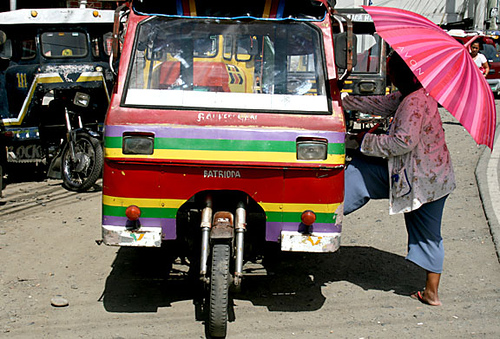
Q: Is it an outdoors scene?
A: Yes, it is outdoors.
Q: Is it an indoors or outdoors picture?
A: It is outdoors.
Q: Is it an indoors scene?
A: No, it is outdoors.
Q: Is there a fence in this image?
A: No, there are no fences.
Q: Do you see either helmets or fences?
A: No, there are no fences or helmets.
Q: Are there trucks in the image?
A: No, there are no trucks.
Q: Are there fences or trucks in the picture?
A: No, there are no trucks or fences.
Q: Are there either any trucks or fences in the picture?
A: No, there are no trucks or fences.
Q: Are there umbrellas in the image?
A: Yes, there is an umbrella.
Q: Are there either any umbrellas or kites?
A: Yes, there is an umbrella.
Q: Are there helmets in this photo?
A: No, there are no helmets.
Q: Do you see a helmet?
A: No, there are no helmets.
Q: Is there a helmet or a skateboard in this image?
A: No, there are no helmets or skateboards.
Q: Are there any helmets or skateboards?
A: No, there are no helmets or skateboards.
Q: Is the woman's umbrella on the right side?
A: Yes, the umbrella is on the right of the image.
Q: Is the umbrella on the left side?
A: No, the umbrella is on the right of the image.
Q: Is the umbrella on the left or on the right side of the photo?
A: The umbrella is on the right of the image.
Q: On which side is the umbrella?
A: The umbrella is on the right of the image.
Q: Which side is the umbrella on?
A: The umbrella is on the right of the image.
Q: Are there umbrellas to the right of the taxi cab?
A: Yes, there is an umbrella to the right of the taxi cab.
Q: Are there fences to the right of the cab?
A: No, there is an umbrella to the right of the cab.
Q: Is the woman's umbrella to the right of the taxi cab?
A: Yes, the umbrella is to the right of the taxi cab.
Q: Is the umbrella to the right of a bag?
A: No, the umbrella is to the right of the taxi cab.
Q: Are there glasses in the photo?
A: No, there are no glasses.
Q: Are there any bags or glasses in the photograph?
A: No, there are no glasses or bags.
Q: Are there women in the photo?
A: Yes, there is a woman.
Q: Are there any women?
A: Yes, there is a woman.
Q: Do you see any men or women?
A: Yes, there is a woman.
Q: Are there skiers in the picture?
A: No, there are no skiers.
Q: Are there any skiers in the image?
A: No, there are no skiers.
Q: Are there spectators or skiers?
A: No, there are no skiers or spectators.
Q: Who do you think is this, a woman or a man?
A: This is a woman.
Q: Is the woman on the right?
A: Yes, the woman is on the right of the image.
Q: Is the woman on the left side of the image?
A: No, the woman is on the right of the image.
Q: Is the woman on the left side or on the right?
A: The woman is on the right of the image.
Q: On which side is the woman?
A: The woman is on the right of the image.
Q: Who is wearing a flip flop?
A: The woman is wearing a flip flop.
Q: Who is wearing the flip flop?
A: The woman is wearing a flip flop.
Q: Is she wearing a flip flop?
A: Yes, the woman is wearing a flip flop.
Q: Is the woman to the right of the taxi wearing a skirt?
A: No, the woman is wearing a flip flop.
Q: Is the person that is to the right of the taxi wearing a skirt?
A: No, the woman is wearing a flip flop.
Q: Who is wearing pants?
A: The woman is wearing pants.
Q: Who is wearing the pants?
A: The woman is wearing pants.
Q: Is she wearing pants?
A: Yes, the woman is wearing pants.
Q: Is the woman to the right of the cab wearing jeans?
A: No, the woman is wearing pants.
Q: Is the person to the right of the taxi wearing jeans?
A: No, the woman is wearing pants.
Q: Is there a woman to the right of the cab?
A: Yes, there is a woman to the right of the cab.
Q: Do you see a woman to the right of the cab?
A: Yes, there is a woman to the right of the cab.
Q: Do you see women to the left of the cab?
A: No, the woman is to the right of the cab.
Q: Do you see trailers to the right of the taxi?
A: No, there is a woman to the right of the taxi.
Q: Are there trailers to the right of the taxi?
A: No, there is a woman to the right of the taxi.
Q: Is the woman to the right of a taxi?
A: Yes, the woman is to the right of a taxi.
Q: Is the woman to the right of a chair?
A: No, the woman is to the right of a taxi.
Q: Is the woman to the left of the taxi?
A: No, the woman is to the right of the taxi.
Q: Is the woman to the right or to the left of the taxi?
A: The woman is to the right of the taxi.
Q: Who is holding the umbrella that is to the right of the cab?
A: The woman is holding the umbrella.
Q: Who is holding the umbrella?
A: The woman is holding the umbrella.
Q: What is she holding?
A: The woman is holding the umbrella.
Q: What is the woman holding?
A: The woman is holding the umbrella.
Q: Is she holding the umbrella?
A: Yes, the woman is holding the umbrella.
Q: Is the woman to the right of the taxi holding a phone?
A: No, the woman is holding the umbrella.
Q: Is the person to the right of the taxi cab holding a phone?
A: No, the woman is holding the umbrella.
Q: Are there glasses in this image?
A: No, there are no glasses.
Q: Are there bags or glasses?
A: No, there are no glasses or bags.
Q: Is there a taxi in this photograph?
A: Yes, there is a taxi.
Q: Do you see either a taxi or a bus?
A: Yes, there is a taxi.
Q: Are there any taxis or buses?
A: Yes, there is a taxi.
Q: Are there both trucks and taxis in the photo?
A: No, there is a taxi but no trucks.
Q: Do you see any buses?
A: No, there are no buses.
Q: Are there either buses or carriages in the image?
A: No, there are no buses or carriages.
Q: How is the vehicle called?
A: The vehicle is a taxi.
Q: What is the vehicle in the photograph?
A: The vehicle is a taxi.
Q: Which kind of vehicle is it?
A: The vehicle is a taxi.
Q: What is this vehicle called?
A: This is a taxi.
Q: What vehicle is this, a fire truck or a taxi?
A: This is a taxi.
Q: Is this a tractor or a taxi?
A: This is a taxi.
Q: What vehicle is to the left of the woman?
A: The vehicle is a taxi.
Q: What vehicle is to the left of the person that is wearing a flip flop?
A: The vehicle is a taxi.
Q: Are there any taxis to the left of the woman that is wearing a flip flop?
A: Yes, there is a taxi to the left of the woman.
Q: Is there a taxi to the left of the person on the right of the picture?
A: Yes, there is a taxi to the left of the woman.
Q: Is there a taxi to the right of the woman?
A: No, the taxi is to the left of the woman.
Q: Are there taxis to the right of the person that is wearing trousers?
A: No, the taxi is to the left of the woman.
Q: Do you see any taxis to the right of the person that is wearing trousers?
A: No, the taxi is to the left of the woman.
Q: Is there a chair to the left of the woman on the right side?
A: No, there is a taxi to the left of the woman.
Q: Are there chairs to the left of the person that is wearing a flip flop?
A: No, there is a taxi to the left of the woman.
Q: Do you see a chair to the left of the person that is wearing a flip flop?
A: No, there is a taxi to the left of the woman.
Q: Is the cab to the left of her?
A: Yes, the cab is to the left of a woman.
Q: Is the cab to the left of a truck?
A: No, the cab is to the left of a woman.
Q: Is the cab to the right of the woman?
A: No, the cab is to the left of the woman.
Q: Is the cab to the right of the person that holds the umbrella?
A: No, the cab is to the left of the woman.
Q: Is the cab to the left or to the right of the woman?
A: The cab is to the left of the woman.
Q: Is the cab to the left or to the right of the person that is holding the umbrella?
A: The cab is to the left of the woman.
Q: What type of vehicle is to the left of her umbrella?
A: The vehicle is a taxi.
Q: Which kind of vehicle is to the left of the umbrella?
A: The vehicle is a taxi.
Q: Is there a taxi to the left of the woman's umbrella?
A: Yes, there is a taxi to the left of the umbrella.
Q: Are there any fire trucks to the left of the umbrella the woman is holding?
A: No, there is a taxi to the left of the umbrella.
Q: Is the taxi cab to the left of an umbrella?
A: Yes, the taxi cab is to the left of an umbrella.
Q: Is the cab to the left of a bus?
A: No, the cab is to the left of an umbrella.